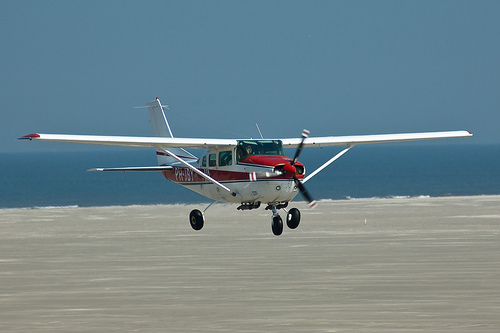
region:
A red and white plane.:
[206, 74, 316, 224]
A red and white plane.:
[162, 26, 347, 258]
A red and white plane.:
[143, 93, 270, 285]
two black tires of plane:
[260, 200, 308, 247]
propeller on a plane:
[227, 120, 324, 223]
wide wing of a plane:
[35, 113, 478, 161]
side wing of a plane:
[77, 156, 175, 197]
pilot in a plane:
[227, 137, 304, 192]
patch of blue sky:
[263, 65, 395, 122]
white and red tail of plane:
[115, 65, 187, 144]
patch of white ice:
[263, 247, 428, 312]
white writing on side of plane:
[155, 158, 198, 186]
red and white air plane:
[142, 80, 431, 274]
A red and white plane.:
[168, 91, 253, 198]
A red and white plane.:
[202, 130, 314, 319]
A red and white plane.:
[191, 118, 287, 235]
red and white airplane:
[19, 53, 478, 240]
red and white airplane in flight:
[20, 72, 474, 239]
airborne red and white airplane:
[18, 80, 475, 237]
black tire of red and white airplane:
[177, 208, 204, 233]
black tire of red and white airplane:
[266, 215, 283, 236]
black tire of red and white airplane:
[283, 206, 303, 232]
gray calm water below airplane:
[13, 242, 437, 319]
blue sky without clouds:
[10, 10, 235, 87]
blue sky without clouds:
[181, 10, 378, 119]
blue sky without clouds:
[324, 17, 482, 112]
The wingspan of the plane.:
[10, 106, 480, 161]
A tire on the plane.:
[180, 205, 206, 237]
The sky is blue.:
[191, 26, 494, 76]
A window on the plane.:
[210, 145, 231, 166]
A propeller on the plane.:
[240, 126, 325, 211]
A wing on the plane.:
[10, 117, 236, 167]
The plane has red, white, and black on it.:
[2, 81, 454, 261]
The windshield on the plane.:
[233, 140, 283, 157]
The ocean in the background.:
[11, 157, 77, 185]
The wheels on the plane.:
[168, 195, 325, 252]